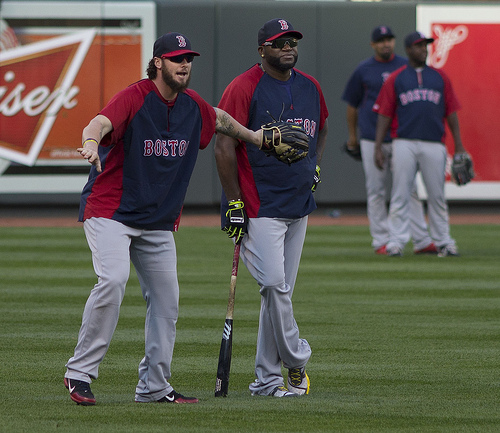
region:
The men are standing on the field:
[39, 33, 370, 405]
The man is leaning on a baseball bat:
[218, 29, 332, 399]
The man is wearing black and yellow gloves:
[219, 192, 271, 256]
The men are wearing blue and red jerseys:
[56, 28, 446, 395]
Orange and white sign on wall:
[6, 30, 168, 212]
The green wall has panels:
[104, 28, 432, 180]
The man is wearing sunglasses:
[135, 29, 205, 99]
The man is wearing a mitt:
[249, 111, 327, 191]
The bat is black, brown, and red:
[205, 236, 261, 400]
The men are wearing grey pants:
[43, 36, 469, 413]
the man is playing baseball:
[225, 4, 342, 391]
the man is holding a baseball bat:
[215, 171, 245, 409]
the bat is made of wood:
[210, 217, 245, 407]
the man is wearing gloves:
[210, 158, 348, 238]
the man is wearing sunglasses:
[222, 2, 315, 67]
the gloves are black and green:
[203, 177, 263, 254]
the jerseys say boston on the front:
[75, 78, 203, 222]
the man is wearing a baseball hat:
[128, 15, 230, 77]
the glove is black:
[191, 91, 321, 186]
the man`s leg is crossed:
[206, 163, 341, 404]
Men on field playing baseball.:
[67, 15, 365, 413]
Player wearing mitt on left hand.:
[251, 120, 311, 170]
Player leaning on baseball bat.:
[210, 215, 250, 405]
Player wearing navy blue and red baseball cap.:
[255, 10, 300, 40]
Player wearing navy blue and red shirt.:
[75, 70, 215, 240]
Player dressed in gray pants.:
[61, 210, 186, 405]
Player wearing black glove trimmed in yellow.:
[220, 195, 250, 241]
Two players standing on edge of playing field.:
[336, 20, 481, 257]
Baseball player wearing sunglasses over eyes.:
[266, 36, 300, 51]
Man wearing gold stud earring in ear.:
[258, 49, 273, 63]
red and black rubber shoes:
[52, 370, 101, 407]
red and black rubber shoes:
[67, 364, 95, 411]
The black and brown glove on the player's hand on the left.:
[255, 117, 318, 161]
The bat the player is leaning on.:
[216, 232, 258, 395]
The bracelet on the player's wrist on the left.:
[72, 133, 107, 153]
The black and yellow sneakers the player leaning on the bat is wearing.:
[246, 360, 321, 399]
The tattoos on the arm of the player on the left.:
[214, 102, 257, 150]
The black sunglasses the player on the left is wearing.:
[161, 48, 196, 66]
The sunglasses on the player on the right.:
[259, 30, 303, 49]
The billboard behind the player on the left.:
[0, 17, 140, 176]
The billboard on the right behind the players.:
[418, 7, 499, 163]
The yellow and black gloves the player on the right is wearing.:
[214, 149, 334, 249]